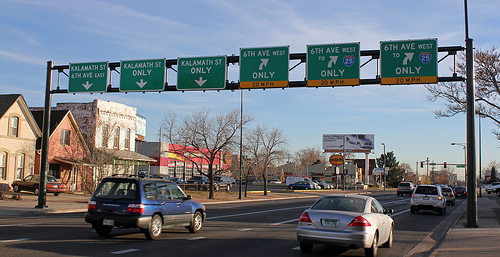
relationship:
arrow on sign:
[81, 79, 97, 89] [66, 63, 108, 93]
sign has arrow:
[122, 62, 162, 91] [132, 76, 154, 90]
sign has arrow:
[174, 54, 226, 93] [189, 74, 214, 86]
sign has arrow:
[241, 46, 288, 90] [255, 53, 274, 71]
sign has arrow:
[382, 39, 439, 85] [397, 49, 416, 69]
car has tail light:
[71, 173, 215, 240] [85, 203, 103, 210]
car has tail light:
[71, 173, 215, 240] [127, 205, 147, 217]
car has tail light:
[295, 186, 391, 256] [297, 209, 320, 224]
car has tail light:
[295, 186, 391, 256] [352, 211, 372, 230]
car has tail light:
[406, 178, 452, 220] [408, 192, 420, 201]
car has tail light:
[406, 178, 452, 220] [437, 192, 446, 206]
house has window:
[0, 94, 38, 191] [9, 114, 22, 135]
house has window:
[0, 94, 38, 191] [0, 150, 8, 187]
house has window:
[0, 94, 38, 191] [14, 150, 32, 181]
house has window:
[41, 105, 88, 192] [59, 123, 78, 150]